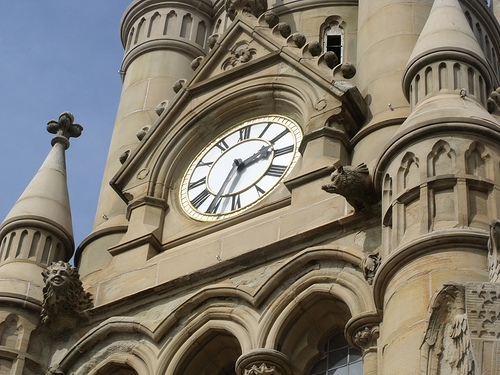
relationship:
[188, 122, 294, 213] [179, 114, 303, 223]
roman numerals on clock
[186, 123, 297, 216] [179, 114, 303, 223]
2:35 on clock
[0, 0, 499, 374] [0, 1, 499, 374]
tower made of stone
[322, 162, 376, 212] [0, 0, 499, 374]
gargoyle on tower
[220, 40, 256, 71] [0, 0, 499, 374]
crab on tower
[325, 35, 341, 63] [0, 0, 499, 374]
window on tower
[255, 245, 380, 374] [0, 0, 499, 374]
arch on tower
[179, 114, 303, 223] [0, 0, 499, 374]
clock on tower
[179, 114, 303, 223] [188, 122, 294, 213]
clock have roman numerals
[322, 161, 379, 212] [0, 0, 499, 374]
wolf on tower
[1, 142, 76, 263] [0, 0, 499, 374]
cone on tower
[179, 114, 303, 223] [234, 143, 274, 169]
clock has a short hand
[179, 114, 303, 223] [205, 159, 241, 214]
clock has a long hand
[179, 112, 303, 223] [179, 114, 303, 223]
gold on clock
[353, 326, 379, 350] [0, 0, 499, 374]
flourish on tower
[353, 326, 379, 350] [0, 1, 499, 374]
flourish made of stone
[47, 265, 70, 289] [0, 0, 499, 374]
face on tower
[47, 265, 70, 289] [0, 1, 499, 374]
face made of stone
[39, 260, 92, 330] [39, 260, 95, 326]
statue with hair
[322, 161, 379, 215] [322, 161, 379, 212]
wolf of wolf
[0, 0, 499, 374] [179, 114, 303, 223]
tower has a clock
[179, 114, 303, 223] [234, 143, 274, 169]
clock has a black short hand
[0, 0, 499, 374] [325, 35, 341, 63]
tower has a window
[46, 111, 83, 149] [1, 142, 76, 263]
top of cone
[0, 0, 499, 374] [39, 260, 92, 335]
tower with statue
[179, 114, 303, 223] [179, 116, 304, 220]
clock has a face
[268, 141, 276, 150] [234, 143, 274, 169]
point on short hand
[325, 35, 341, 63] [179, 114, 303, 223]
window above clock